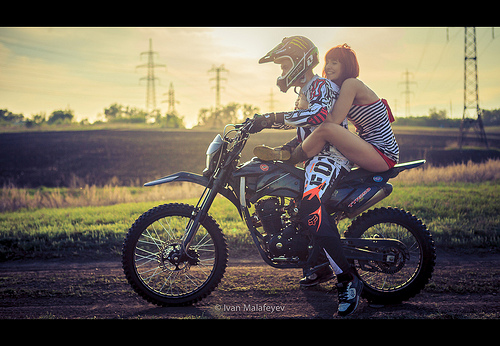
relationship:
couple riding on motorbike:
[253, 36, 407, 171] [113, 119, 441, 315]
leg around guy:
[301, 123, 382, 174] [264, 38, 368, 313]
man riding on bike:
[264, 38, 368, 313] [113, 119, 441, 315]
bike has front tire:
[113, 119, 441, 315] [120, 203, 229, 304]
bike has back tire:
[113, 119, 441, 315] [346, 205, 437, 307]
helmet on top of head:
[262, 35, 321, 89] [280, 56, 311, 85]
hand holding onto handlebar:
[247, 115, 274, 132] [261, 118, 270, 126]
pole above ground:
[447, 28, 492, 146] [448, 142, 494, 160]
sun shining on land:
[216, 28, 272, 61] [3, 184, 249, 239]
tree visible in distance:
[50, 107, 72, 126] [1, 82, 150, 131]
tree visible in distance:
[104, 103, 137, 122] [1, 82, 150, 131]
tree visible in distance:
[428, 106, 447, 121] [390, 68, 493, 120]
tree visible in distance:
[198, 107, 226, 123] [100, 79, 287, 121]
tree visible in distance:
[33, 111, 46, 124] [1, 82, 150, 131]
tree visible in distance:
[2, 110, 22, 126] [1, 82, 150, 131]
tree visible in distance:
[484, 108, 500, 124] [390, 68, 493, 120]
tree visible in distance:
[243, 103, 259, 119] [100, 79, 287, 121]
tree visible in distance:
[152, 106, 171, 126] [100, 79, 287, 121]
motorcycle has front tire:
[113, 119, 441, 315] [120, 203, 229, 304]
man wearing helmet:
[264, 38, 368, 313] [262, 35, 321, 89]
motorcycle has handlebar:
[113, 119, 441, 315] [261, 118, 270, 126]